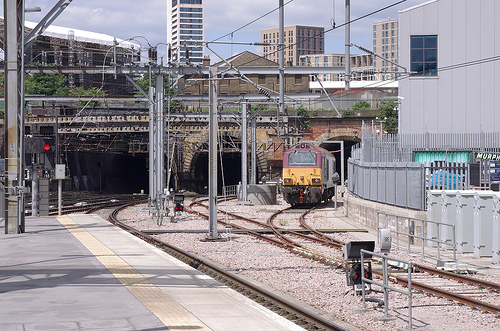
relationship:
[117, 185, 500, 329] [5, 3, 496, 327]
tracks for railroad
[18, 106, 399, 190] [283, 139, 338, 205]
overpass above train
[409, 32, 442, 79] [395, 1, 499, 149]
window on building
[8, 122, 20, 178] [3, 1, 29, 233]
rust on pole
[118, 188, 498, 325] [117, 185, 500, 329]
gravel between tracks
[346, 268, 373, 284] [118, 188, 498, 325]
lights in gravel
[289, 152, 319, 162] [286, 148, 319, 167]
wipers on window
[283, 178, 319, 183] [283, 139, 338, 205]
headlights on train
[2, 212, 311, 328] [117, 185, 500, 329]
walkway next to tracks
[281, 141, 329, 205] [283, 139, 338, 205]
front of train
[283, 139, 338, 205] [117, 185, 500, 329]
train on tracks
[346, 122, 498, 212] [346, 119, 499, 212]
fencing of metal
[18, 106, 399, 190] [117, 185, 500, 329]
bridge over tracks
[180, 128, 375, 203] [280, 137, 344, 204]
tunnel for trains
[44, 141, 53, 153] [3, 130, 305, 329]
light at station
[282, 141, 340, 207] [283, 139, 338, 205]
engine of train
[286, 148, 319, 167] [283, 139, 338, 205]
window of train